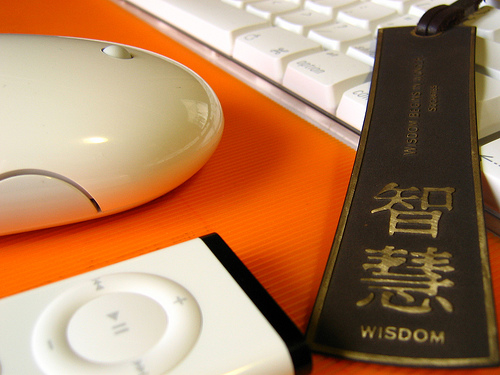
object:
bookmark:
[303, 25, 500, 371]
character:
[357, 182, 455, 313]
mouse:
[0, 33, 225, 236]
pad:
[0, 0, 500, 375]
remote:
[0, 231, 315, 375]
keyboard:
[115, 0, 500, 238]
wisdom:
[360, 325, 444, 344]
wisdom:
[403, 120, 418, 155]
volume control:
[30, 272, 203, 375]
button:
[0, 173, 101, 237]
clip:
[416, 0, 482, 34]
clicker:
[103, 45, 132, 59]